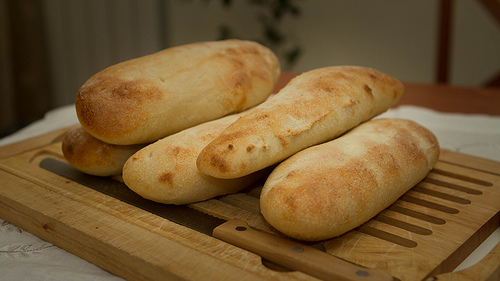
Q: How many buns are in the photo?
A: 5.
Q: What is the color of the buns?
A: Brown.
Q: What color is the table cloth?
A: White.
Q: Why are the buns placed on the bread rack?
A: To cool.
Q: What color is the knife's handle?
A: Brown.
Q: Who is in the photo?
A: No one.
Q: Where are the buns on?
A: A bread rack.